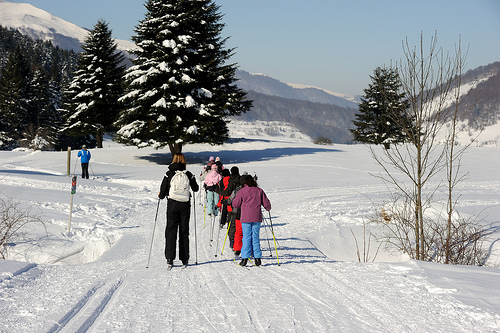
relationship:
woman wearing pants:
[159, 154, 199, 264] [165, 197, 191, 263]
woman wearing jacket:
[159, 154, 199, 264] [156, 165, 197, 201]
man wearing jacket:
[76, 145, 91, 180] [78, 148, 91, 165]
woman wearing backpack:
[159, 154, 199, 264] [169, 170, 193, 204]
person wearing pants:
[232, 175, 273, 266] [238, 221, 262, 259]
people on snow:
[201, 155, 272, 268] [0, 141, 498, 331]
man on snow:
[76, 145, 91, 180] [0, 141, 498, 331]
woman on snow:
[159, 154, 199, 264] [0, 141, 498, 331]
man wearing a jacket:
[76, 145, 91, 180] [78, 148, 91, 165]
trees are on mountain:
[1, 25, 362, 146] [0, 1, 499, 145]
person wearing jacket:
[232, 175, 273, 266] [231, 184, 273, 226]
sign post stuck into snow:
[66, 193, 74, 235] [0, 141, 498, 331]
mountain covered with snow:
[0, 1, 499, 145] [2, 2, 365, 106]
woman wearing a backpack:
[159, 154, 199, 264] [169, 170, 193, 204]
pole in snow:
[65, 146, 73, 179] [0, 141, 498, 331]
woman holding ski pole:
[159, 154, 199, 264] [145, 197, 162, 271]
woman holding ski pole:
[159, 154, 199, 264] [192, 192, 199, 267]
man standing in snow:
[76, 145, 91, 180] [0, 141, 498, 331]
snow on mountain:
[2, 2, 365, 106] [0, 1, 499, 145]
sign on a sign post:
[70, 174, 77, 197] [66, 193, 74, 235]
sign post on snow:
[66, 193, 74, 235] [0, 141, 498, 331]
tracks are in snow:
[46, 213, 399, 332] [0, 141, 498, 331]